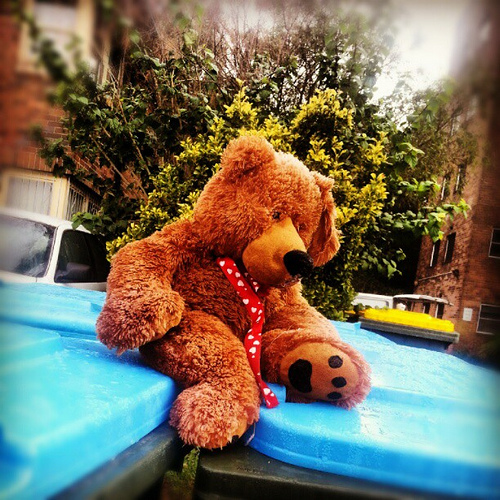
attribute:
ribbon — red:
[219, 256, 282, 408]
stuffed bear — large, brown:
[93, 128, 369, 450]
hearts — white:
[217, 259, 243, 288]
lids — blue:
[1, 277, 498, 495]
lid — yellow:
[358, 302, 458, 332]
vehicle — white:
[0, 207, 112, 297]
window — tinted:
[53, 226, 115, 284]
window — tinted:
[0, 213, 53, 278]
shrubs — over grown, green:
[0, 2, 486, 323]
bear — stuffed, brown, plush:
[96, 129, 373, 451]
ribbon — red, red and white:
[213, 250, 281, 410]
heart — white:
[218, 254, 224, 264]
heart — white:
[223, 262, 236, 275]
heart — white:
[256, 387, 275, 402]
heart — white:
[252, 333, 262, 351]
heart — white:
[240, 330, 253, 340]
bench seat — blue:
[243, 319, 496, 495]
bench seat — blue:
[0, 279, 180, 498]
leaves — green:
[2, 0, 472, 319]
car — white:
[0, 202, 113, 289]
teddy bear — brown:
[93, 123, 373, 454]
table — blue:
[246, 316, 498, 495]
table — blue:
[1, 279, 173, 498]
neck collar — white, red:
[210, 256, 278, 403]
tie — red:
[216, 255, 280, 409]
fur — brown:
[92, 132, 371, 451]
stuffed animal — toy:
[94, 132, 372, 451]